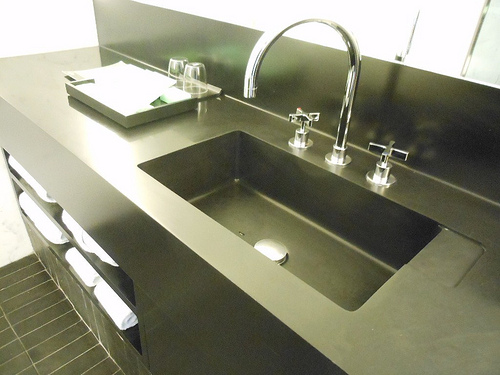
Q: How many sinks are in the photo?
A: One.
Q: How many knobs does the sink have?
A: Two.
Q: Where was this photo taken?
A: A bathroom.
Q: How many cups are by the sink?
A: Two.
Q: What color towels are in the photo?
A: White.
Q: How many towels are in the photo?
A: Eight.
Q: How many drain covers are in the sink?
A: One.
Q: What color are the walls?
A: White.